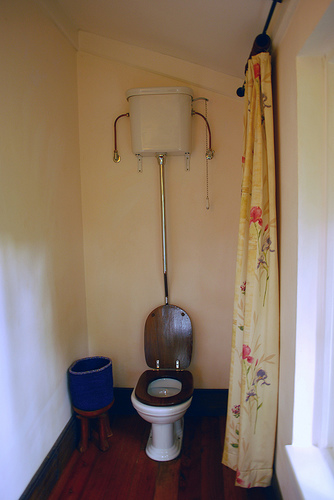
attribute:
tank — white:
[125, 86, 196, 157]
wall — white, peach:
[84, 29, 246, 407]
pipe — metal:
[159, 154, 169, 302]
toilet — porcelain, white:
[132, 308, 192, 462]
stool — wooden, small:
[72, 397, 121, 455]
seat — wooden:
[134, 305, 194, 406]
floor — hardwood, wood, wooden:
[55, 410, 279, 498]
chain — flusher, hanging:
[190, 93, 217, 212]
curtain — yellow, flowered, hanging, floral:
[221, 52, 282, 494]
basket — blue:
[70, 356, 113, 408]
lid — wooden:
[143, 301, 193, 373]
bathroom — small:
[2, 0, 334, 498]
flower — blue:
[244, 369, 269, 408]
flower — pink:
[249, 202, 265, 232]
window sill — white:
[285, 439, 334, 498]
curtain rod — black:
[236, 0, 279, 96]